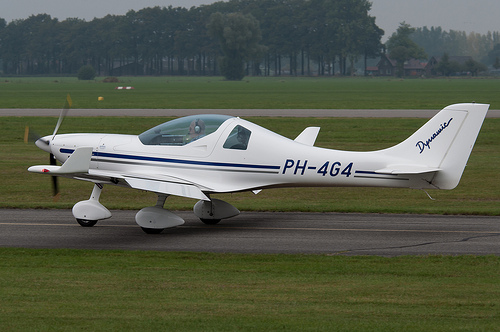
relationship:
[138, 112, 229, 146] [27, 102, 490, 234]
cockpit of airplane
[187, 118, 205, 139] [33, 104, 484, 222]
pilot of plane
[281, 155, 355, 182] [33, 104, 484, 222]
number on plane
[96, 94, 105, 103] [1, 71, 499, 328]
object on ground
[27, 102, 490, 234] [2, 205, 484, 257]
airplane on runway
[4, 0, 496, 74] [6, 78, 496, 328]
trees by airport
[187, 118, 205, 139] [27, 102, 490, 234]
pilot in airplane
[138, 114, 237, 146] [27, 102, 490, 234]
window on airplane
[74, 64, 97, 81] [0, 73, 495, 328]
bush on grass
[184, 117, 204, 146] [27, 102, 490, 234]
pilot in airplane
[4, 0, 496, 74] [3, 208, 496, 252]
trees by runway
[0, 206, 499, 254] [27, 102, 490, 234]
runway beneath airplane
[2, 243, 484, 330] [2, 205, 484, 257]
grass next to runway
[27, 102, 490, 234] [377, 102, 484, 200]
airplane has tail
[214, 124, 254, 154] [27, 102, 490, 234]
window on airplane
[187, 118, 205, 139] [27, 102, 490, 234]
pilot flying airplane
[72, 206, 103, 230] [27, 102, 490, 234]
wheel on airplane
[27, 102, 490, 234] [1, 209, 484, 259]
airplane on runway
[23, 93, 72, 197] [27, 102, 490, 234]
propeller of airplane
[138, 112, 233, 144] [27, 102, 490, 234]
window on airplane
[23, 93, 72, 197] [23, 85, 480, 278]
propeller on airplane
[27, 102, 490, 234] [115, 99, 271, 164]
airplane has a canopy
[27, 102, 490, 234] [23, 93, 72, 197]
airplane has propeller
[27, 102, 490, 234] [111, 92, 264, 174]
airplane has a cockpit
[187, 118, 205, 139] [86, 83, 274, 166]
pilot in cockpit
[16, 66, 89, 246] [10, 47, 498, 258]
propeller on front of plane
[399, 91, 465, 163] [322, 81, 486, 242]
name on tail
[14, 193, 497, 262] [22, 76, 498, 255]
runway for plane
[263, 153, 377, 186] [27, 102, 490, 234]
ph-4g4 on side of airplane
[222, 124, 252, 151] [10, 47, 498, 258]
window on plane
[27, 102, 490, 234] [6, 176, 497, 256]
airplane on runway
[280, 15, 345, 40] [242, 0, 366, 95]
leaves on tree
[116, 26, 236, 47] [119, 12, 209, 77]
leaves on tree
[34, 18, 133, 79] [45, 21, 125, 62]
leaves on tree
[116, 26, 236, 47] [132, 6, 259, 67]
leaves on tree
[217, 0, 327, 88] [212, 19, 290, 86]
leaves on tree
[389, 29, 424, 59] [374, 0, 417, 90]
leaves on tree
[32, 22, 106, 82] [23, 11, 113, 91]
leaves on tree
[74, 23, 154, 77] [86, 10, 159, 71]
leaves on tree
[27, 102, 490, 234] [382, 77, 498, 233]
airplane has a tail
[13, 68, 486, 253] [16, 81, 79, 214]
airplane has a propeller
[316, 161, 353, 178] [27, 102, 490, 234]
number on airplane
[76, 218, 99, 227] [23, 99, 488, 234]
wheel of airplane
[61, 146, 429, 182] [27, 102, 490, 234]
stripes down a airplane